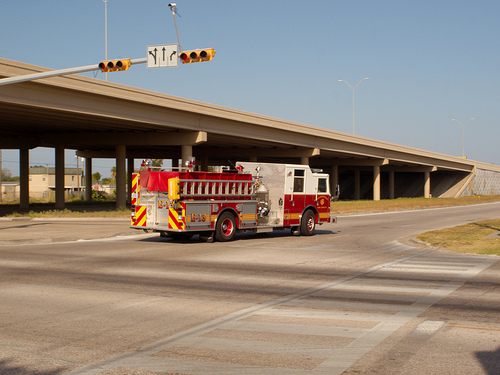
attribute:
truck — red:
[133, 162, 332, 232]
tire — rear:
[215, 210, 235, 243]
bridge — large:
[67, 48, 441, 201]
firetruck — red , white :
[126, 153, 336, 235]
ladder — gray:
[175, 179, 255, 197]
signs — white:
[146, 46, 180, 66]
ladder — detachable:
[168, 175, 259, 202]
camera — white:
[163, 0, 193, 47]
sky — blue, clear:
[0, 0, 495, 173]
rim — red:
[219, 220, 240, 241]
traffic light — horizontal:
[97, 46, 212, 70]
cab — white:
[250, 161, 334, 224]